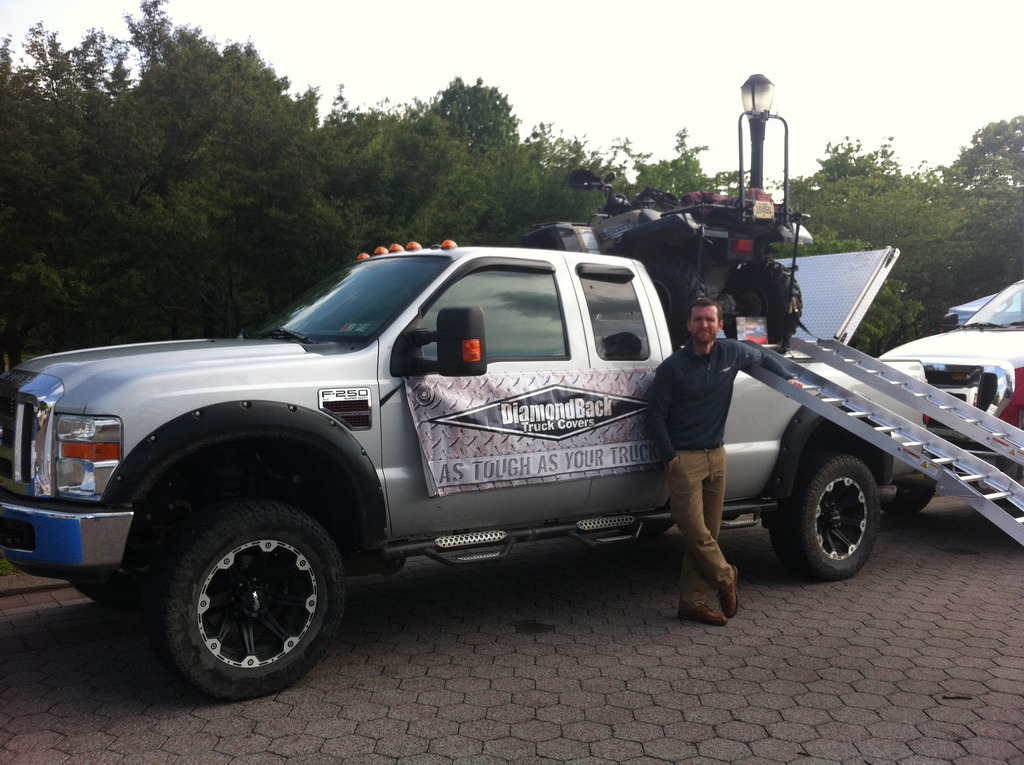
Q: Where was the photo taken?
A: Close to the Diamondback truck.